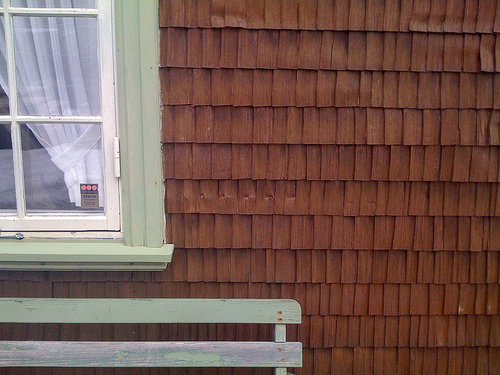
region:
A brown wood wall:
[374, 226, 488, 356]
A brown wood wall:
[298, 274, 370, 374]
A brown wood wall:
[157, 146, 272, 248]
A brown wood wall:
[288, 147, 392, 232]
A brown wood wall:
[395, 133, 496, 234]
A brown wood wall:
[165, 6, 269, 133]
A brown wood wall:
[274, 3, 359, 125]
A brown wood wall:
[360, 12, 498, 157]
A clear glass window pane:
[12, 119, 112, 217]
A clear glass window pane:
[5, 12, 113, 117]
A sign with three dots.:
[78, 178, 104, 214]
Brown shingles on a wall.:
[254, 120, 475, 257]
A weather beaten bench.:
[7, 291, 307, 373]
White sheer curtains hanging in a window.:
[12, 6, 102, 173]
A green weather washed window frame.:
[4, 2, 179, 274]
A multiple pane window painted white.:
[4, 8, 121, 233]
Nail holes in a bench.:
[274, 303, 284, 322]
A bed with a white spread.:
[0, 144, 107, 209]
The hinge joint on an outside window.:
[111, 136, 124, 175]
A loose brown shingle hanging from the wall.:
[477, 24, 497, 74]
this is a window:
[4, 2, 109, 214]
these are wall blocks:
[164, 5, 212, 70]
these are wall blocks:
[209, 154, 275, 224]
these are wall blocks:
[277, 236, 352, 309]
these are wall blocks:
[295, 67, 345, 144]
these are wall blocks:
[299, 215, 353, 279]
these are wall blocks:
[341, 224, 398, 288]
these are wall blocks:
[371, 30, 420, 107]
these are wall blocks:
[364, 190, 424, 253]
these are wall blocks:
[414, 251, 466, 324]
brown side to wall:
[225, 23, 450, 260]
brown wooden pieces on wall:
[277, 35, 437, 180]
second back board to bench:
[18, 339, 308, 373]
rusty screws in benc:
[277, 306, 288, 321]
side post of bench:
[278, 322, 293, 373]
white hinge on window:
[108, 139, 126, 174]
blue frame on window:
[128, 33, 165, 191]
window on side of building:
[0, 105, 127, 236]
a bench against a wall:
[160, 243, 337, 372]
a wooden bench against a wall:
[193, 261, 328, 373]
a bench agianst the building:
[221, 251, 403, 368]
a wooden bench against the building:
[150, 237, 392, 369]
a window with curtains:
[27, 18, 243, 286]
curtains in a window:
[64, 52, 232, 229]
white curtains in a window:
[3, 18, 135, 218]